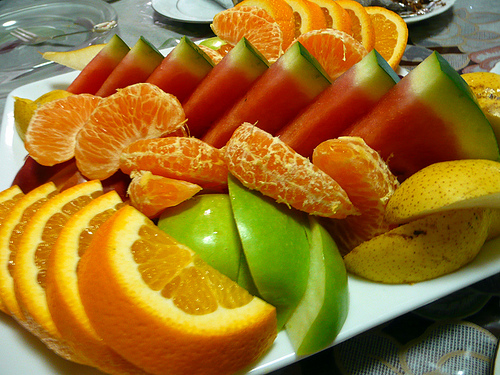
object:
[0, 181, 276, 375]
orange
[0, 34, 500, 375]
plate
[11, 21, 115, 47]
fork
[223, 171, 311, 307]
apple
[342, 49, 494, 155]
meleon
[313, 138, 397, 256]
lemon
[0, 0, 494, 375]
fruit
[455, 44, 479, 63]
table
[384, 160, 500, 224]
pear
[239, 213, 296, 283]
rine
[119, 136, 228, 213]
clementine